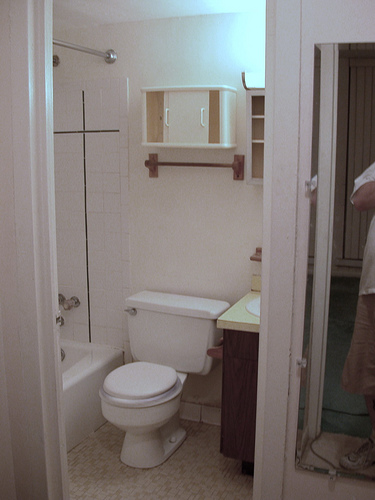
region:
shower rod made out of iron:
[83, 48, 114, 63]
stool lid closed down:
[110, 360, 174, 392]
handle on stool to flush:
[121, 308, 137, 317]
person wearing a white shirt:
[364, 235, 370, 263]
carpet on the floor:
[339, 286, 344, 314]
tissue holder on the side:
[207, 338, 224, 360]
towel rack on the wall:
[144, 155, 246, 178]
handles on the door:
[197, 105, 205, 128]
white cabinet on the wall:
[142, 78, 234, 150]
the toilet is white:
[98, 351, 183, 421]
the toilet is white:
[90, 355, 186, 478]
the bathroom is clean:
[51, 233, 234, 498]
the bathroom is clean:
[62, 223, 260, 495]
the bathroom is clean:
[55, 228, 260, 496]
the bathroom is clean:
[66, 233, 246, 493]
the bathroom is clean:
[60, 235, 235, 490]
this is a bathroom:
[2, 1, 374, 498]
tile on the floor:
[56, 382, 247, 498]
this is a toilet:
[83, 265, 230, 471]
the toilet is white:
[83, 268, 220, 471]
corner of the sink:
[197, 266, 257, 357]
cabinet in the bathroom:
[130, 77, 237, 154]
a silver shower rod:
[43, 8, 129, 74]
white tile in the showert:
[40, 55, 126, 350]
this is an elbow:
[345, 151, 374, 234]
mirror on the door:
[283, 35, 373, 499]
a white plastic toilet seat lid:
[102, 360, 177, 398]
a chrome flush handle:
[122, 308, 138, 314]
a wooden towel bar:
[145, 153, 244, 180]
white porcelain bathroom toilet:
[87, 282, 235, 481]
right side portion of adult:
[337, 146, 373, 480]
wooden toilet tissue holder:
[205, 333, 225, 362]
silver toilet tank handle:
[121, 302, 140, 319]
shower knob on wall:
[59, 291, 82, 315]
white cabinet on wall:
[134, 81, 239, 151]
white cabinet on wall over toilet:
[132, 81, 239, 150]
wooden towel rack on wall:
[137, 152, 246, 184]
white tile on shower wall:
[48, 75, 127, 353]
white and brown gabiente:
[142, 88, 226, 144]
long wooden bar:
[139, 158, 240, 173]